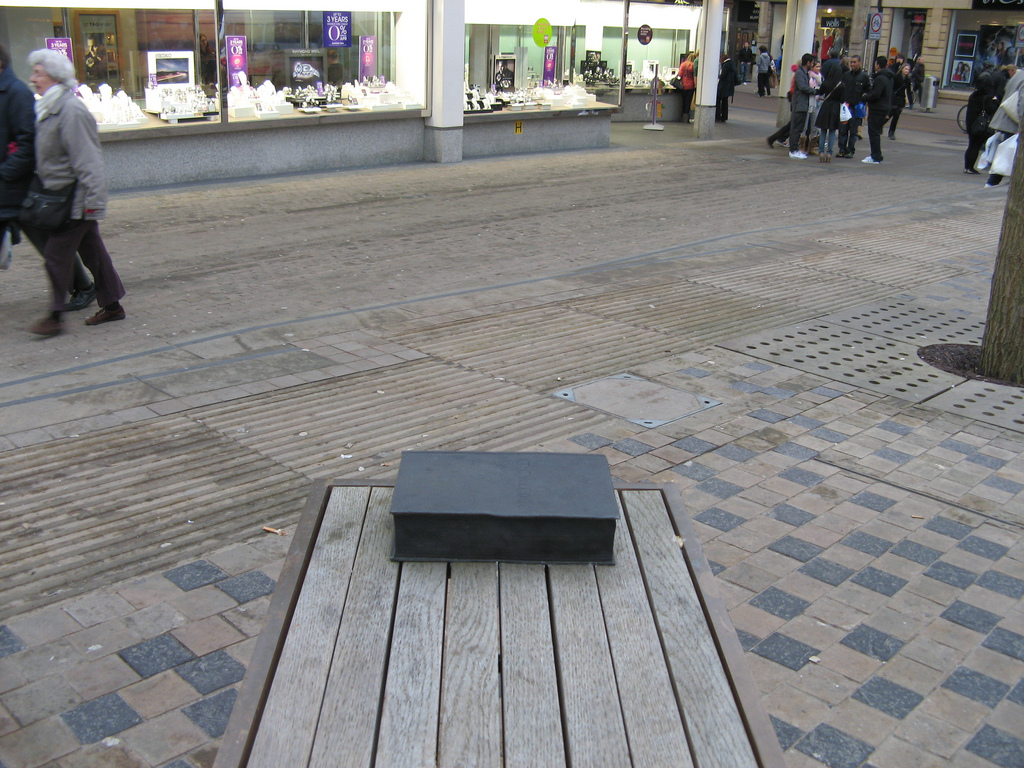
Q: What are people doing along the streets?
A: Window shopping.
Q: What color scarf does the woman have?
A: White.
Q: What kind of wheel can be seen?
A: Part of a bicycle.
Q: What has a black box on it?
A: A wooden bench.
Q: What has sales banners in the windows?
A: Jewelry.